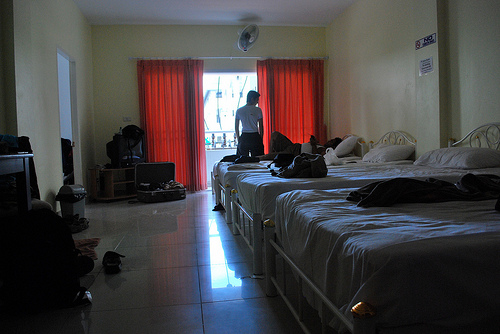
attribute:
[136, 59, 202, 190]
curtain — red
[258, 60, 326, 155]
curtain — red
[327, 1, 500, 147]
wall — white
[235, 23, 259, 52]
fan — fixed, white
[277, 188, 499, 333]
bed — queensize, white, here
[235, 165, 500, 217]
bed — white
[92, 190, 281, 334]
floor — marble, tile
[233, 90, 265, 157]
person — white, standing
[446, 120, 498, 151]
headboard — metal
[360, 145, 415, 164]
pillow — white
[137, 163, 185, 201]
suitcase — full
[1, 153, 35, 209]
table — wooden